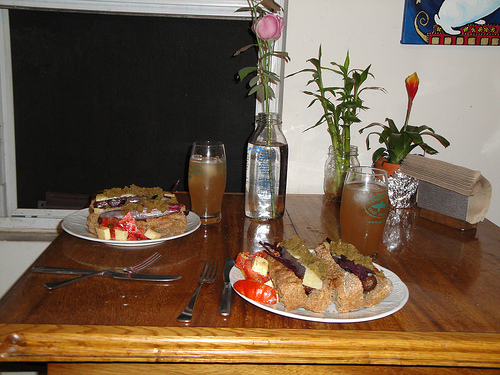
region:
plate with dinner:
[220, 230, 410, 331]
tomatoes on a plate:
[236, 248, 277, 305]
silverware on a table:
[54, 255, 239, 325]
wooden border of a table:
[62, 320, 203, 364]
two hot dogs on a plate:
[273, 255, 388, 305]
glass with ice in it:
[186, 138, 230, 228]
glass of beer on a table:
[332, 153, 392, 273]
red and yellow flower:
[400, 68, 426, 109]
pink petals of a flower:
[246, 13, 292, 43]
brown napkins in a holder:
[373, 119, 498, 248]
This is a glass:
[181, 129, 237, 239]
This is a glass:
[241, 88, 302, 231]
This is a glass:
[337, 160, 399, 265]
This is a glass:
[324, 129, 364, 207]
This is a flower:
[370, 59, 450, 166]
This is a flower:
[305, 45, 382, 148]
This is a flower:
[231, 0, 297, 132]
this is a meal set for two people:
[41, 133, 412, 328]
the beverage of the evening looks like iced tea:
[335, 160, 390, 255]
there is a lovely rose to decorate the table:
[231, 0, 291, 221]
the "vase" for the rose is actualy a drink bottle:
[240, 107, 290, 222]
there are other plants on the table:
[295, 45, 445, 205]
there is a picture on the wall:
[395, 0, 495, 51]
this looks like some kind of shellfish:
[230, 275, 280, 305]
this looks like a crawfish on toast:
[256, 235, 328, 307]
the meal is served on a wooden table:
[1, 185, 493, 365]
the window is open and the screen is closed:
[2, 2, 263, 213]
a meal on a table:
[14, 22, 486, 353]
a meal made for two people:
[54, 70, 475, 339]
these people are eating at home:
[44, 96, 484, 330]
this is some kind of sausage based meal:
[223, 222, 420, 333]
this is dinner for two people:
[54, 143, 426, 328]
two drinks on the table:
[181, 135, 410, 250]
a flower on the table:
[240, 22, 300, 217]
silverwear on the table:
[34, 234, 237, 325]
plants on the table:
[304, 67, 439, 169]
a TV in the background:
[8, 2, 286, 249]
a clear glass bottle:
[240, 110, 288, 223]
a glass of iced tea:
[186, 142, 228, 224]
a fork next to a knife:
[176, 253, 217, 326]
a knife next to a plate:
[217, 255, 235, 324]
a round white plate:
[228, 243, 408, 320]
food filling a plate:
[233, 239, 390, 306]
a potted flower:
[372, 73, 441, 171]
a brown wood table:
[0, 191, 498, 374]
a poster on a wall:
[397, 2, 499, 50]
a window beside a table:
[0, 3, 285, 233]